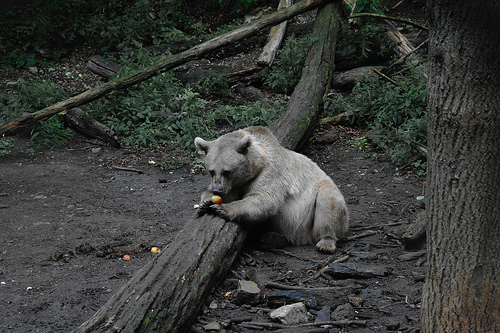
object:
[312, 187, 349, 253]
leg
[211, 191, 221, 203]
apple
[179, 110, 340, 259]
bear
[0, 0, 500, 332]
wooden logs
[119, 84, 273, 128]
plants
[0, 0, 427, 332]
ground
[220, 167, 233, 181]
eyes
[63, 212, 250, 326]
log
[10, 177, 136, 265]
floor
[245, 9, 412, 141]
tree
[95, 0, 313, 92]
dry wood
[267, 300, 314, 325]
rock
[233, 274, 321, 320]
stuff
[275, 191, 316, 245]
tummy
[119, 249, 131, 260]
apple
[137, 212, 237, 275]
trunk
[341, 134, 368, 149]
leaves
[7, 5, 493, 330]
photo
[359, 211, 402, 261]
part